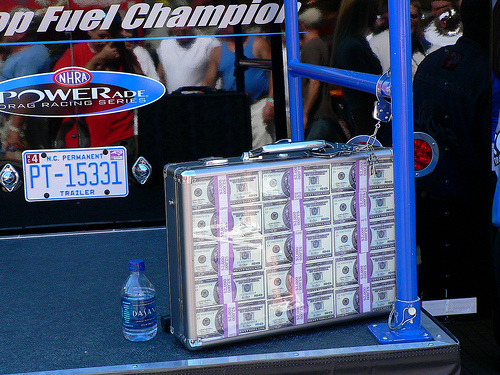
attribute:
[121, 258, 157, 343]
bottle — small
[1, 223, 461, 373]
table — grey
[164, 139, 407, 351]
briefcase — clear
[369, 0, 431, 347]
pole — blue, metal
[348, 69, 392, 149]
handcuffs — silver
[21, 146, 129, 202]
plate — white, blue, metal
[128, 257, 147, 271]
top — blue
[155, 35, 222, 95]
shirt — white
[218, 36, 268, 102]
shirt — blue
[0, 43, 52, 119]
shirt — blue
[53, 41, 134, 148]
shirt — red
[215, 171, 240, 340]
money bands — white, purple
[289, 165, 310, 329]
money bands — white, purple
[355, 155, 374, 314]
money bands — white, purple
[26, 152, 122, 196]
letters — blue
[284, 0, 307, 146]
pole — blue, metal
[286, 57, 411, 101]
pole — blue, metal